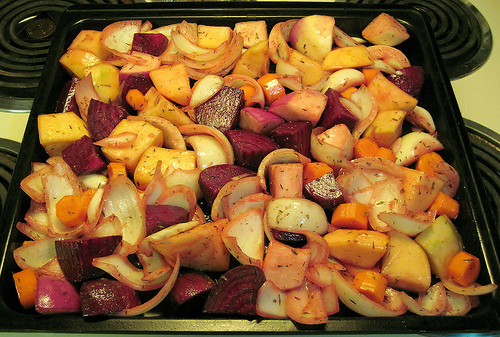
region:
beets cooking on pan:
[78, 270, 137, 320]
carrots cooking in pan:
[51, 193, 96, 230]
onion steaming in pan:
[260, 192, 332, 238]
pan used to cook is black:
[14, 7, 499, 328]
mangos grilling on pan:
[137, 132, 202, 195]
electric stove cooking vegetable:
[2, 2, 77, 93]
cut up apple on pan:
[272, 88, 329, 127]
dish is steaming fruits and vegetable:
[47, 37, 486, 329]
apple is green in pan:
[377, 222, 437, 294]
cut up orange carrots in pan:
[122, 81, 149, 122]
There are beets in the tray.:
[193, 113, 318, 201]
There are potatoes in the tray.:
[322, 223, 434, 284]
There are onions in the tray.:
[97, 255, 194, 312]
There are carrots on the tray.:
[330, 197, 377, 228]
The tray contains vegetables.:
[6, 5, 496, 332]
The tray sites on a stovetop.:
[2, 2, 499, 334]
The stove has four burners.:
[2, 1, 499, 301]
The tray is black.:
[15, 6, 491, 335]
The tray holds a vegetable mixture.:
[11, 9, 497, 334]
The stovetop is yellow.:
[448, 4, 496, 145]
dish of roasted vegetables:
[25, 6, 489, 335]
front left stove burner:
[6, 125, 33, 245]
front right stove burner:
[433, 112, 498, 241]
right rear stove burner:
[332, 9, 489, 84]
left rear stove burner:
[5, 7, 134, 116]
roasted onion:
[222, 182, 274, 267]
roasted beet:
[231, 122, 290, 163]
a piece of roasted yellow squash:
[33, 108, 94, 158]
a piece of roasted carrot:
[326, 195, 371, 225]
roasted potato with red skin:
[33, 274, 80, 314]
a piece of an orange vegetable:
[450, 249, 479, 287]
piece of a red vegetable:
[208, 265, 256, 318]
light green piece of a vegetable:
[35, 113, 82, 140]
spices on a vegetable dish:
[400, 134, 447, 208]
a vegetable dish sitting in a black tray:
[3, 5, 498, 330]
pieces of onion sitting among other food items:
[110, 162, 190, 218]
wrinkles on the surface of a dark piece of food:
[208, 85, 240, 130]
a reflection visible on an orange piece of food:
[262, 73, 278, 95]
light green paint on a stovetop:
[466, 90, 493, 107]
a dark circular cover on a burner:
[434, 5, 476, 49]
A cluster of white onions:
[167, 30, 248, 81]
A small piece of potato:
[323, 225, 395, 267]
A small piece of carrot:
[265, 162, 310, 200]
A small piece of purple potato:
[83, 96, 128, 140]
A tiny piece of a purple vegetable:
[86, 95, 128, 140]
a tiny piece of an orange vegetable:
[267, 165, 305, 198]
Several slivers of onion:
[167, 27, 244, 77]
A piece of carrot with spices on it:
[266, 162, 305, 198]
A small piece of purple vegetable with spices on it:
[88, 97, 129, 139]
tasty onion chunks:
[168, 29, 243, 77]